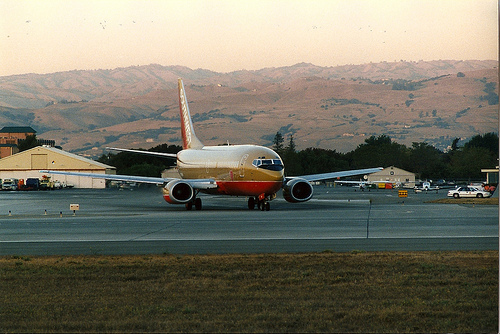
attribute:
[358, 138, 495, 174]
trees — tall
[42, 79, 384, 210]
plane — red, brown, black, blue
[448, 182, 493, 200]
white car — white 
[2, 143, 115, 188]
building — tan, white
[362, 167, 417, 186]
building — white, tan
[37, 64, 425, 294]
plane — small, private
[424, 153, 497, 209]
cars — white, black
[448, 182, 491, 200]
car — white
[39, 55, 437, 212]
airplane — jet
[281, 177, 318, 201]
left engine — propellor 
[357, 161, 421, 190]
building — tan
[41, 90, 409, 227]
plane — bronze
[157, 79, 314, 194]
plane — yellow, red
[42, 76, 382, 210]
airplane — jet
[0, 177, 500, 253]
pavement — cement 